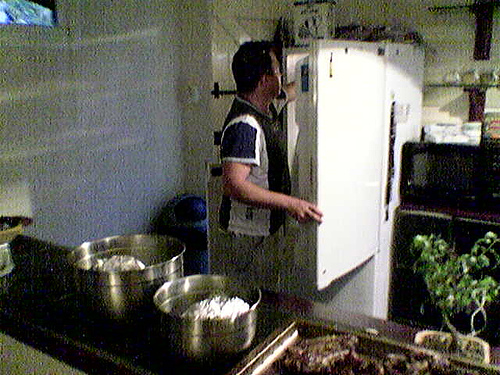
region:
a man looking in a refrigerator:
[207, 18, 396, 284]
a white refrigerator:
[294, 47, 403, 314]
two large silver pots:
[54, 230, 264, 360]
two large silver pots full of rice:
[61, 223, 262, 365]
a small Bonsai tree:
[406, 230, 489, 365]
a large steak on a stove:
[281, 329, 366, 372]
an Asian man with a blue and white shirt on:
[201, 33, 324, 238]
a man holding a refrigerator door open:
[215, 33, 387, 264]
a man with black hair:
[221, 34, 296, 109]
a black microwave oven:
[393, 139, 497, 205]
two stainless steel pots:
[50, 220, 276, 372]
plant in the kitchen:
[408, 258, 498, 335]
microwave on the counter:
[421, 156, 485, 217]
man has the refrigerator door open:
[229, 86, 364, 227]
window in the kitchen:
[14, 2, 83, 32]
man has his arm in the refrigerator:
[279, 71, 342, 121]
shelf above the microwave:
[425, 56, 497, 97]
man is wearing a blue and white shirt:
[233, 110, 278, 176]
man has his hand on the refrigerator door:
[271, 201, 343, 246]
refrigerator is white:
[339, 99, 368, 229]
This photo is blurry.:
[42, 37, 461, 327]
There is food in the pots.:
[90, 238, 247, 346]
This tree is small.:
[386, 223, 498, 336]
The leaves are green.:
[392, 253, 484, 315]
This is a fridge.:
[278, 30, 405, 266]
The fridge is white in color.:
[281, 58, 383, 260]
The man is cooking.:
[215, 48, 313, 259]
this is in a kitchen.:
[71, 30, 461, 334]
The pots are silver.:
[80, 234, 253, 363]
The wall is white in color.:
[36, 54, 183, 215]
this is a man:
[225, 59, 306, 215]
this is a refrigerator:
[324, 53, 390, 226]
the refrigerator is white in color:
[326, 88, 373, 136]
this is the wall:
[34, 45, 125, 135]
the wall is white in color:
[23, 100, 155, 202]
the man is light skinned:
[226, 173, 258, 200]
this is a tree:
[416, 233, 494, 344]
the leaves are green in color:
[431, 243, 453, 287]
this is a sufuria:
[164, 310, 244, 350]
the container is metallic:
[177, 319, 219, 356]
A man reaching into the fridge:
[222, 30, 375, 261]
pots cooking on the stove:
[51, 223, 254, 348]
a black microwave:
[401, 135, 499, 211]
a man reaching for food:
[202, 44, 349, 275]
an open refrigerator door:
[266, 24, 398, 314]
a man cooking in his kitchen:
[211, 33, 336, 300]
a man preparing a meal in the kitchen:
[211, 10, 330, 279]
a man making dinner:
[206, 34, 346, 276]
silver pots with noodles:
[64, 229, 275, 373]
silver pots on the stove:
[61, 238, 275, 365]